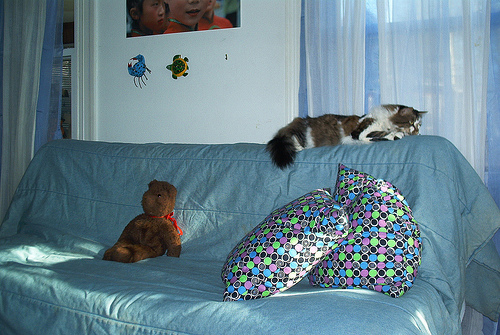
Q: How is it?
A: Sleeping.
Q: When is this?
A: Daytime.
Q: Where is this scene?
A: In a living room.